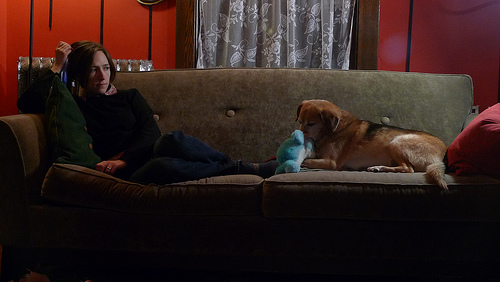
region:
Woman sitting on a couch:
[21, 27, 229, 180]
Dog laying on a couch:
[260, 90, 455, 190]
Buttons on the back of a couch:
[140, 97, 240, 133]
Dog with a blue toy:
[260, 90, 462, 178]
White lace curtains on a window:
[190, 0, 351, 77]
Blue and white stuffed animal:
[266, 123, 316, 180]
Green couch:
[123, 68, 487, 262]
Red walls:
[434, 27, 492, 67]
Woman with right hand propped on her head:
[17, 36, 139, 136]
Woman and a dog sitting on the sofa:
[17, 31, 477, 226]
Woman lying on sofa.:
[13, 38, 275, 182]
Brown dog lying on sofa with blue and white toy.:
[275, 91, 452, 200]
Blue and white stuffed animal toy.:
[269, 116, 316, 181]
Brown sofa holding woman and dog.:
[6, 68, 499, 258]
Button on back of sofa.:
[214, 98, 248, 124]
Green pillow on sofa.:
[43, 73, 103, 175]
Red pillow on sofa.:
[441, 100, 496, 179]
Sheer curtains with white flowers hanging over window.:
[191, 0, 375, 75]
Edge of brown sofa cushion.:
[259, 166, 495, 226]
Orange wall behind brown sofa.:
[424, 13, 496, 70]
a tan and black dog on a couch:
[297, 100, 451, 187]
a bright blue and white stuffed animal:
[275, 129, 312, 177]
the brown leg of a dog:
[370, 133, 438, 176]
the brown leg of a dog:
[301, 141, 347, 171]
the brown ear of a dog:
[295, 99, 306, 118]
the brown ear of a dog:
[321, 108, 340, 130]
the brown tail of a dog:
[421, 158, 453, 183]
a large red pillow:
[445, 100, 497, 175]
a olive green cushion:
[267, 164, 457, 211]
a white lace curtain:
[195, 1, 352, 68]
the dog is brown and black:
[292, 101, 452, 167]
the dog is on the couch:
[303, 84, 450, 185]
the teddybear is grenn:
[268, 130, 328, 173]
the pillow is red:
[450, 104, 499, 164]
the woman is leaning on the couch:
[43, 34, 295, 196]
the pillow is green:
[46, 88, 103, 167]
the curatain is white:
[199, 16, 362, 68]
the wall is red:
[14, 9, 160, 35]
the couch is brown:
[283, 76, 463, 98]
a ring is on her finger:
[99, 156, 117, 178]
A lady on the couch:
[40, 29, 270, 194]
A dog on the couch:
[276, 92, 451, 184]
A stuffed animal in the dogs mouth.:
[274, 114, 361, 197]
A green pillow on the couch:
[31, 71, 122, 177]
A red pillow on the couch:
[431, 100, 491, 183]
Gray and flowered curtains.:
[167, 1, 390, 78]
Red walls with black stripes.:
[20, 7, 176, 57]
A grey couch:
[26, 35, 481, 240]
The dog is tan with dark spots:
[276, 85, 478, 192]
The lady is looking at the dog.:
[45, 31, 162, 131]